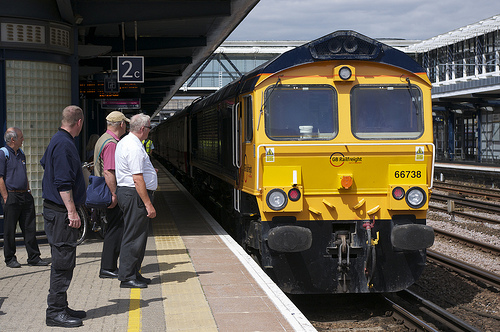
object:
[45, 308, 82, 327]
feet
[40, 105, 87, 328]
commuters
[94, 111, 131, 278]
man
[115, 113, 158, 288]
man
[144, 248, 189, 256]
shadow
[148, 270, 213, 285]
shadow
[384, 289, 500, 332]
rails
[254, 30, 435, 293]
front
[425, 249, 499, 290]
tracks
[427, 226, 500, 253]
tracks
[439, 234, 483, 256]
gravel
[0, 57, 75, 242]
front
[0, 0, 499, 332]
depot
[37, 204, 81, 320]
pant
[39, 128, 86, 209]
shirt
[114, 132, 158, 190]
shirt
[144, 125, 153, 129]
sunglasses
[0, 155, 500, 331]
ground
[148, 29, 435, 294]
train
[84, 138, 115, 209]
bag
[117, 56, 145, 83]
sign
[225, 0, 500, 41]
sky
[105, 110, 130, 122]
hat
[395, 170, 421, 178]
number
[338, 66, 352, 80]
head light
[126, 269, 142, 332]
line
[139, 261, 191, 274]
shadow